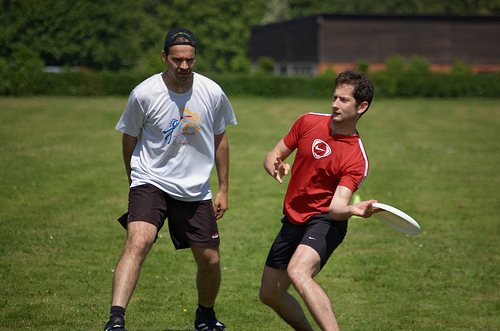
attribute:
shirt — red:
[278, 108, 375, 220]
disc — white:
[362, 196, 430, 244]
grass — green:
[1, 96, 500, 329]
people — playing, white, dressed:
[83, 23, 436, 330]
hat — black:
[154, 25, 204, 46]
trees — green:
[1, 1, 301, 88]